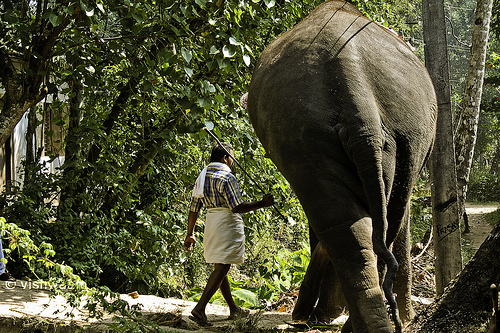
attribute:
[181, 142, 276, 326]
man — light skinned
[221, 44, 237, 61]
leaf — green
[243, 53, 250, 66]
leaf — green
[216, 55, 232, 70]
leaf — green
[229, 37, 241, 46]
leaf — green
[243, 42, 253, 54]
leaf — green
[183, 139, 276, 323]
person — walking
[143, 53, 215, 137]
leaves — green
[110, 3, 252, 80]
leaves — green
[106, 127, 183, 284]
leaves — green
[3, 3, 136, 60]
leaves — green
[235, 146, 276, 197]
leaves — green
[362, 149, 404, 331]
tail — long, curved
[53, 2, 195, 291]
foliage — green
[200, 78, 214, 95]
leaves — green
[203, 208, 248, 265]
skirt — white